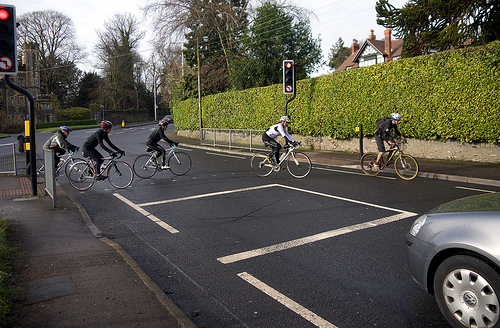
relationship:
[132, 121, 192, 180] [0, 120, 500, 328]
cyclist crossing road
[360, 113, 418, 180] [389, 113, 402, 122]
cyclist wearing helmet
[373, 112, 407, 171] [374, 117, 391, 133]
cyclist has a backpack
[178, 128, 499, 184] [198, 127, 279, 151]
sidewalk has a railing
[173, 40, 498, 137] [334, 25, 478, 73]
bushes in front of a building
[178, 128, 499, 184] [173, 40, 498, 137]
sidewalk bordered by a hedge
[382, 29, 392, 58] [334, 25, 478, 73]
chimney on a building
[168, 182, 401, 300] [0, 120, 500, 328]
lines in road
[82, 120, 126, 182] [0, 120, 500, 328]
cyclist in road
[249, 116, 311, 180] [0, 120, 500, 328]
bicyclist crossing road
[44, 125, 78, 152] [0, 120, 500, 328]
cyclist crossing road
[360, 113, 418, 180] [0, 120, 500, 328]
cyclist crossing road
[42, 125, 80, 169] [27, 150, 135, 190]
cyclist riding bicycles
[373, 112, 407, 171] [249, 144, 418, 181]
cyclist riding bicycles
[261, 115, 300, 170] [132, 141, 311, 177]
bicyclist riding bicycles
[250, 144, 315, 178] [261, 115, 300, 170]
bike ridden by a bicyclist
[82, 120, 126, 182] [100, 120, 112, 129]
cyclist wearing a helmet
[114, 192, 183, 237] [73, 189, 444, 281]
lines on road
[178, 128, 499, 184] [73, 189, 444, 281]
sidewalk near road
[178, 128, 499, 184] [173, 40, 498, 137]
sidewalk with a hedge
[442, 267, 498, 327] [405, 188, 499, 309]
tire on car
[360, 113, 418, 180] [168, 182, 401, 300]
cyclist crossing street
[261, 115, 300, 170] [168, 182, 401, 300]
bicyclist crossing street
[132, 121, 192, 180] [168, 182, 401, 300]
cyclist crossing street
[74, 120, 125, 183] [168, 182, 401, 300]
cyclist crossing street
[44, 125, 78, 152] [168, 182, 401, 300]
cyclist crossing street